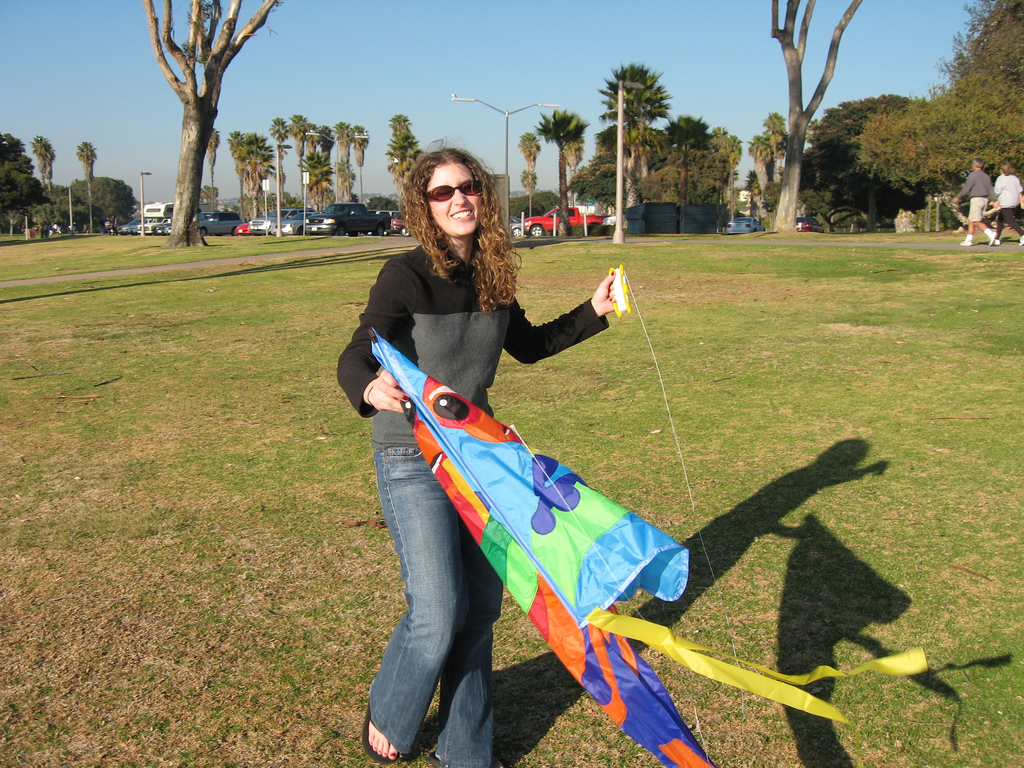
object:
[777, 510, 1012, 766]
shadow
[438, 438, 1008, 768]
shadow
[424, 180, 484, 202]
glasses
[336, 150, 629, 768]
woman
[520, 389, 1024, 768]
ground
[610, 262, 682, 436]
twine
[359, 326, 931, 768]
kite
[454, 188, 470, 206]
nose